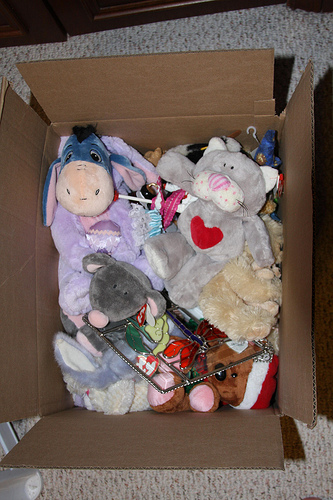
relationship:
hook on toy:
[243, 120, 268, 142] [256, 126, 284, 165]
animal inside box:
[42, 124, 284, 415] [0, 49, 317, 471]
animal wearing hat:
[42, 124, 284, 415] [231, 338, 282, 416]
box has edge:
[0, 49, 317, 471] [1, 39, 317, 480]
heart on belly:
[185, 212, 237, 250] [177, 197, 246, 260]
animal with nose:
[42, 124, 284, 415] [83, 301, 123, 329]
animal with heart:
[42, 124, 284, 415] [188, 215, 223, 248]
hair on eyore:
[69, 120, 101, 141] [34, 116, 170, 323]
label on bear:
[135, 354, 158, 377] [53, 331, 155, 415]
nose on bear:
[213, 359, 227, 379] [142, 322, 284, 417]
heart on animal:
[190, 216, 223, 251] [141, 133, 279, 311]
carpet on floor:
[1, 5, 327, 106] [6, 7, 326, 121]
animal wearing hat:
[42, 124, 284, 415] [230, 353, 279, 410]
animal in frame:
[42, 124, 284, 415] [83, 297, 266, 393]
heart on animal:
[190, 216, 223, 251] [42, 124, 284, 415]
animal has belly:
[42, 124, 284, 415] [175, 197, 245, 260]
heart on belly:
[190, 216, 223, 251] [175, 197, 245, 260]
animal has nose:
[42, 124, 284, 415] [87, 308, 109, 327]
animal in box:
[42, 124, 284, 415] [0, 49, 317, 471]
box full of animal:
[0, 49, 317, 471] [42, 124, 284, 415]